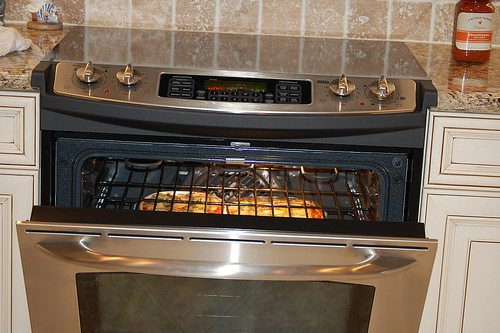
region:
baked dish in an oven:
[137, 188, 327, 218]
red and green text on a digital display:
[202, 78, 270, 93]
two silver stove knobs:
[73, 58, 143, 86]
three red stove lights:
[318, 97, 405, 108]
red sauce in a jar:
[450, 1, 495, 64]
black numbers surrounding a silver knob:
[319, 73, 361, 105]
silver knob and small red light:
[318, 72, 358, 102]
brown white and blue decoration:
[22, 0, 64, 30]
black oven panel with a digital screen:
[156, 70, 313, 104]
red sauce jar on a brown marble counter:
[405, 0, 499, 112]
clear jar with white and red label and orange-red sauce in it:
[450, 1, 494, 64]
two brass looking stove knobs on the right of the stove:
[326, 75, 396, 102]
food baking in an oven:
[137, 187, 324, 221]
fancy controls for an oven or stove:
[157, 70, 313, 106]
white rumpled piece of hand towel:
[2, 23, 33, 58]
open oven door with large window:
[15, 203, 437, 328]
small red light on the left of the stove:
[102, 86, 111, 93]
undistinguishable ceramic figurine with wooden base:
[25, 1, 62, 31]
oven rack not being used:
[84, 159, 378, 221]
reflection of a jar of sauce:
[445, 57, 492, 93]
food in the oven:
[71, 149, 353, 217]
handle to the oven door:
[96, 245, 369, 305]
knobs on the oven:
[61, 60, 410, 122]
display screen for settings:
[166, 75, 308, 106]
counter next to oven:
[429, 48, 497, 105]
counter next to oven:
[4, 26, 36, 63]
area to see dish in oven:
[124, 282, 331, 325]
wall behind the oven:
[111, 9, 347, 31]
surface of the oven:
[105, 33, 356, 66]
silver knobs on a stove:
[74, 60, 399, 103]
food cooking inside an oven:
[136, 189, 327, 224]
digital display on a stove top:
[154, 72, 316, 108]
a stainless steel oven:
[15, 20, 439, 330]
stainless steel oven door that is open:
[13, 204, 443, 331]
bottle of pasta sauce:
[449, 2, 496, 65]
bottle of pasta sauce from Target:
[449, 1, 494, 65]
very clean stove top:
[41, 24, 431, 88]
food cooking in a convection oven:
[84, 154, 373, 224]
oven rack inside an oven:
[87, 158, 372, 223]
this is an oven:
[61, 150, 393, 241]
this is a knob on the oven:
[354, 62, 400, 103]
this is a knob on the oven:
[330, 61, 355, 101]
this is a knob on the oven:
[117, 54, 139, 94]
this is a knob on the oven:
[58, 44, 104, 92]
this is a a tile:
[299, 0, 347, 71]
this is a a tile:
[350, 4, 385, 84]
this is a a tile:
[172, 5, 218, 80]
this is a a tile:
[81, 5, 133, 66]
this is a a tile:
[393, 5, 428, 34]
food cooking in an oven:
[11, 35, 448, 318]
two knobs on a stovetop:
[322, 67, 402, 109]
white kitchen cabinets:
[418, 120, 498, 323]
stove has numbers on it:
[201, 71, 231, 97]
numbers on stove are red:
[205, 71, 225, 93]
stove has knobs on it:
[314, 70, 364, 105]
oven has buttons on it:
[154, 63, 331, 114]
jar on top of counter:
[434, 5, 498, 66]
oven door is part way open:
[56, 138, 436, 328]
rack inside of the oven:
[111, 163, 365, 225]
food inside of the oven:
[148, 176, 327, 224]